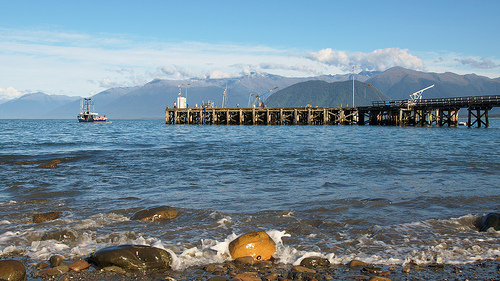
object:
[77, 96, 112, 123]
ship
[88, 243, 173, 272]
stone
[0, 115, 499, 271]
water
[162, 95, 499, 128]
bridge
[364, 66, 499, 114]
mountains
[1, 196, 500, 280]
shore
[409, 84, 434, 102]
crane